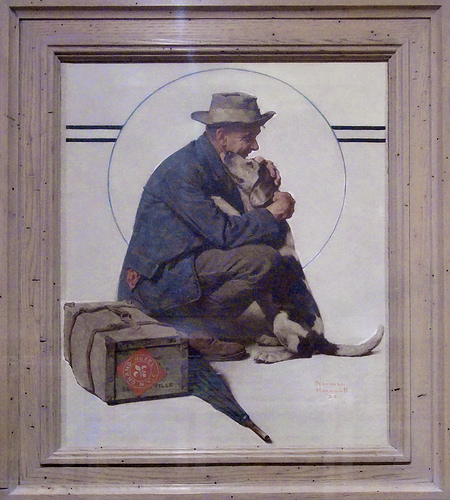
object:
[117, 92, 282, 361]
man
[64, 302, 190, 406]
case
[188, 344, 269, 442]
umbrella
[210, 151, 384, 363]
dog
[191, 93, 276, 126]
hat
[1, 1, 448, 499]
frame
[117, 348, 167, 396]
sticker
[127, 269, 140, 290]
rag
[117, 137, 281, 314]
jacket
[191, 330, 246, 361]
boot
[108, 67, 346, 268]
circle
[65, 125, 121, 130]
stripe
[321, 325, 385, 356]
tail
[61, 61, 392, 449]
norman rockwell